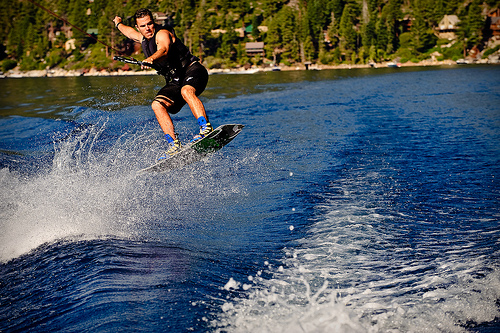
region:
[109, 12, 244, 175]
middle aged man wave boarding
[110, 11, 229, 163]
man wave boarding wearing black swim shorts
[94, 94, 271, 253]
bottom half of wave boarder on lake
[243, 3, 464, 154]
view of lake with shore line in distance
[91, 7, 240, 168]
man with look of concentration on face while wave boarding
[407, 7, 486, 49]
view of blurry distant house among trees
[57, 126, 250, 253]
water spray against wave board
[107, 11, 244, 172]
man practicing water sports wearing black life jacket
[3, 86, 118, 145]
calm section of lake interrupted by waves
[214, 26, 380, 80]
long view of lake front houses and beaches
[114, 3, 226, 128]
this is a man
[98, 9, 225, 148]
the man is sea surfing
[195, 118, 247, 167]
this is the surf board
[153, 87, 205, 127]
these are the legs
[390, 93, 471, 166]
this is the sea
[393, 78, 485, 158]
the sea is blue in color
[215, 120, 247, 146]
this is the surf board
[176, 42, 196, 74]
this is the costume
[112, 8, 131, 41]
the hand is behind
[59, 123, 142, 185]
the water is splashy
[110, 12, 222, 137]
this is a man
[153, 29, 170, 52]
the man is light skinned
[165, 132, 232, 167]
this is a surfboard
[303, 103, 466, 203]
this is a water body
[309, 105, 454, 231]
the water is calm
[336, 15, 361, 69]
this is a tree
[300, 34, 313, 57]
the leaves are green in color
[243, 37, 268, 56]
this is a house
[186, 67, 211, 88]
this is a short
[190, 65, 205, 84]
the short is black in color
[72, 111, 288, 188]
man's waterboard is out of the water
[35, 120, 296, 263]
splash from the waterboard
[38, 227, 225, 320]
water is dark crystal blue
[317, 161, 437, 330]
foam on the water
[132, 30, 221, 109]
skier has on safety vest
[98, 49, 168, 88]
man is holding the handle to rope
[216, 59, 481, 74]
shoreline along the water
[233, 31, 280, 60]
house above the shoreline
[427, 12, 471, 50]
house that is up the hill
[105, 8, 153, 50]
skier's arm is in the air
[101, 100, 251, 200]
board under the man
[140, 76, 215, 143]
legs of the man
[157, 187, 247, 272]
water below the man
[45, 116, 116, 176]
water in the air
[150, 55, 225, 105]
shorts on the man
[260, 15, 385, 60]
trees in the distance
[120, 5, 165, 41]
head of the man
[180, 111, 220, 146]
foot of the man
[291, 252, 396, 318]
white water next to man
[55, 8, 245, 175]
one man in the air